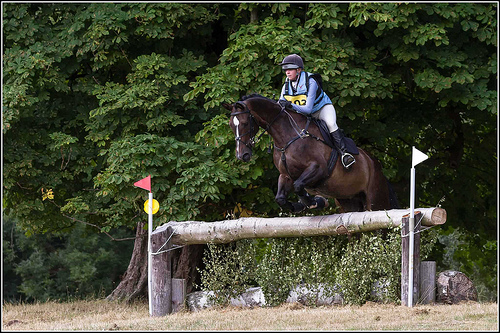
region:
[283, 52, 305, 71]
a blue helmet on a rider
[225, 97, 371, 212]
a brown steed jumping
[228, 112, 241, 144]
a white mark on the face of a horse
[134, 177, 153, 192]
a small red flag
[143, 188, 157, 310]
a round yellow sign on a pole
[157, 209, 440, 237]
a wooden birch log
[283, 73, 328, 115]
blue jacket on the small jockey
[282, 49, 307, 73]
blue helmet on the small jockey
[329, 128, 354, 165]
black boot on the small jockey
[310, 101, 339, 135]
white pants on the small jockey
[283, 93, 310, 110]
yellow number on the small jockey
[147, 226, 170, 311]
wooden stump on horse jump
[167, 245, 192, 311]
wooden stump on horse jump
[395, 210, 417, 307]
wooden stump on horse jump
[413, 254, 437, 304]
wooden stump on horse jump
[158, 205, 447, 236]
wooden stump on horse jump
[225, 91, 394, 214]
a dark brown horse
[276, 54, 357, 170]
an equestrian in blue clothes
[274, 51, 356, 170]
a girl riding a horse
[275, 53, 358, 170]
a girl in a safety helmet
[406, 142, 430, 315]
a small yellow flag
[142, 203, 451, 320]
a wooden hurdle for horses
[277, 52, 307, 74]
a black riding helmet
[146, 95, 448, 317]
A horse jumps a log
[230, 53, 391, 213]
A peron riding a horse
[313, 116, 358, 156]
A black saddle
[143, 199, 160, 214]
A yellow circle on a pole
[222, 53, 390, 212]
a person on a horse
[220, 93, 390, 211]
the horse is brown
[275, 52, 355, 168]
a person with a helmet on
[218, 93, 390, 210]
the horse is jumping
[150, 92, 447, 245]
the horse jumps over the tree trunk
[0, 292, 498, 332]
the grass is dried out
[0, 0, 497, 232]
the leaves are all green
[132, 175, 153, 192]
the flag is red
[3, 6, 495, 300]
the forest in the background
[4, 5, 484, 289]
A forest in the background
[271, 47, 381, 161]
The person on the horse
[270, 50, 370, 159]
A person on the horse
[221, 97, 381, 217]
The brown horse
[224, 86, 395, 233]
A brown horse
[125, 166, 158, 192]
The flag to the left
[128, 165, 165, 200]
A red flag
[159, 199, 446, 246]
A vertical log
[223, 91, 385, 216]
brown and black horse jumping in air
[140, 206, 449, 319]
jumping posts using real tree trunks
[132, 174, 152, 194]
small red triangle shaped flag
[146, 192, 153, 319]
silver metal post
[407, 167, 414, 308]
small silver metal post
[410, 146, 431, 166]
small white triangle shaped flag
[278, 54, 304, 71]
dark gray safety helmet